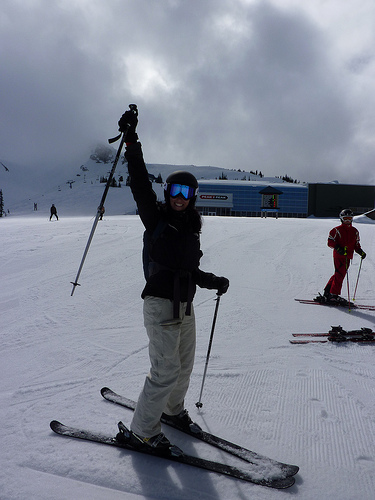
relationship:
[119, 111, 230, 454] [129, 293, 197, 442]
woman wearing pants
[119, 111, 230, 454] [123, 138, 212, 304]
woman wearing jacket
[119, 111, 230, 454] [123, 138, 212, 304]
woman wearing a jacket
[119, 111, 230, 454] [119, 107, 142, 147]
woman wearing a glove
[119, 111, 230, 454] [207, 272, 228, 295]
woman wearing a glove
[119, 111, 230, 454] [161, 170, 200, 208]
woman wearing a helmet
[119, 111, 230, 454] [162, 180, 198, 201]
woman wearing goggles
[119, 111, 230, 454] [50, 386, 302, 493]
woman standing on skis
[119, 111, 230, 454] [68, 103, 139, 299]
woman holding ski pole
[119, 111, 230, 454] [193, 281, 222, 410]
woman holding ski pole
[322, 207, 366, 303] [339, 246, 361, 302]
man holding ski poles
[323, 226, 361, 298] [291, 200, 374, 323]
outfit used for ice skating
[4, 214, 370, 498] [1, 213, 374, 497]
ice covers ground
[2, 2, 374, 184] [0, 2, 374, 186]
clouds are in sky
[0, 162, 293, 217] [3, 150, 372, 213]
mountain in background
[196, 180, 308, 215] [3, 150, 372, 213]
building in background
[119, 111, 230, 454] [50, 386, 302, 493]
woman wearing skis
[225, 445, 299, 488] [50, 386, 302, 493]
snow on skis